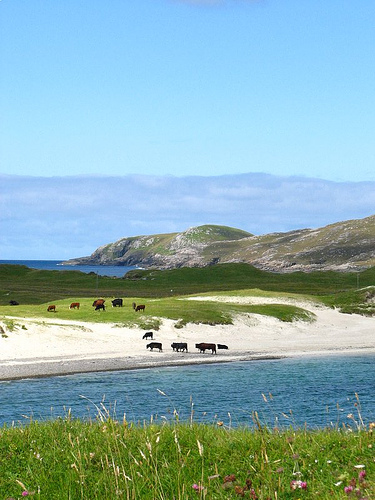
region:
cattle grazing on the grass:
[39, 293, 149, 318]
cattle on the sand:
[141, 331, 231, 358]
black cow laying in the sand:
[216, 343, 230, 352]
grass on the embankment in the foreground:
[6, 414, 374, 498]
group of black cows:
[142, 329, 232, 354]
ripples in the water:
[4, 368, 374, 415]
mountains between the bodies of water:
[98, 224, 374, 271]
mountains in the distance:
[4, 175, 374, 254]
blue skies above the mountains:
[4, 2, 366, 179]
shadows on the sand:
[148, 346, 215, 361]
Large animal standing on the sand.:
[197, 340, 217, 357]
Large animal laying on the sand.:
[215, 340, 236, 357]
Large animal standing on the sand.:
[170, 338, 193, 364]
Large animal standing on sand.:
[143, 339, 177, 362]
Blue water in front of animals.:
[171, 368, 265, 421]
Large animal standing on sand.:
[137, 327, 154, 335]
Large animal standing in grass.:
[133, 300, 143, 306]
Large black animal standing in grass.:
[110, 294, 125, 312]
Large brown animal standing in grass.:
[90, 296, 109, 303]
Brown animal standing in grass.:
[63, 294, 96, 321]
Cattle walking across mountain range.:
[6, 293, 229, 352]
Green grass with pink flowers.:
[25, 421, 371, 491]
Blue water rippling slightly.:
[144, 377, 374, 409]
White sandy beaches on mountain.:
[25, 331, 118, 362]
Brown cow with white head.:
[66, 301, 79, 308]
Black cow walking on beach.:
[143, 340, 163, 350]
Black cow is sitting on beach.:
[218, 344, 229, 349]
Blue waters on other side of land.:
[71, 265, 134, 271]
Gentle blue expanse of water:
[0, 353, 374, 431]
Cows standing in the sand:
[138, 330, 216, 357]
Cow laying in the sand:
[214, 340, 231, 351]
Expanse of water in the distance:
[0, 258, 143, 278]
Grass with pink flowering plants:
[0, 393, 373, 498]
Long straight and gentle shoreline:
[0, 343, 373, 385]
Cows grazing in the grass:
[42, 293, 148, 314]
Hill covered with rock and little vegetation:
[65, 213, 373, 278]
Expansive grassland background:
[0, 263, 373, 332]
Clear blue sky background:
[1, 0, 373, 177]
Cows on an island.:
[24, 291, 228, 355]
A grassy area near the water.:
[8, 407, 373, 498]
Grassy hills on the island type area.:
[56, 210, 371, 287]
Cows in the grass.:
[6, 292, 154, 317]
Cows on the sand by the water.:
[139, 324, 232, 356]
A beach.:
[7, 311, 372, 382]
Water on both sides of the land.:
[7, 220, 373, 438]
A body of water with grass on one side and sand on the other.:
[0, 350, 373, 433]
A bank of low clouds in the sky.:
[4, 167, 374, 257]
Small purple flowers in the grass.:
[180, 459, 373, 499]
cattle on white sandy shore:
[134, 327, 228, 355]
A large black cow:
[193, 341, 223, 358]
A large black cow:
[170, 337, 190, 354]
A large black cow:
[144, 340, 165, 353]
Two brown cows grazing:
[130, 300, 146, 313]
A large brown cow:
[64, 297, 82, 310]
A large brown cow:
[43, 302, 58, 311]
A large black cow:
[110, 295, 126, 307]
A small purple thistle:
[219, 470, 237, 484]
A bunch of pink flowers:
[288, 479, 309, 491]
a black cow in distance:
[169, 341, 188, 352]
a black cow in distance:
[193, 340, 214, 353]